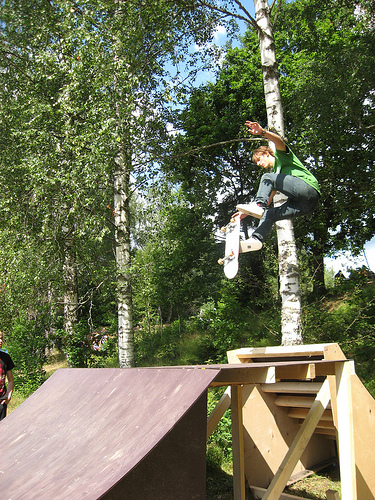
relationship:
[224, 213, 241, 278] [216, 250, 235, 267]
skateboard has wheels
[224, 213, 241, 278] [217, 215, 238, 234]
skateboard has wheels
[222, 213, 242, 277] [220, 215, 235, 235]
skateboard has two wheels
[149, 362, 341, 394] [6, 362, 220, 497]
platform near ramp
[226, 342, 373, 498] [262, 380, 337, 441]
ramp has steps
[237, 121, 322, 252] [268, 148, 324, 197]
skateboarder wearing green t-shirt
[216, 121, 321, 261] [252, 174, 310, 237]
man wearing jeans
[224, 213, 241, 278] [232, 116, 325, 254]
skateboard under boy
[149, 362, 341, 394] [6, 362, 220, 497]
platform beside ramp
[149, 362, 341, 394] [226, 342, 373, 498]
platform beside ramp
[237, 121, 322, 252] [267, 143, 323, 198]
skateboarder wearing green shirt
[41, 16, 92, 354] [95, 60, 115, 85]
birch tree has leaves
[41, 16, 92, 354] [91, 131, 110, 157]
birch tree has leaves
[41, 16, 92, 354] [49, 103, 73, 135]
birch tree has leaves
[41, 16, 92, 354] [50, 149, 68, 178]
birch tree has leaves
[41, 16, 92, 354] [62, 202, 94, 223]
birch tree has leaves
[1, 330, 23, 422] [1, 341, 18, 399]
boy wearing t-shirt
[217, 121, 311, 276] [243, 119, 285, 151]
man has arm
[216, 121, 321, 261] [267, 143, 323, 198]
man wearing green shirt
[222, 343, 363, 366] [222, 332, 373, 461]
stairs made of wood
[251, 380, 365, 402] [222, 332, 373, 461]
stairs made of wood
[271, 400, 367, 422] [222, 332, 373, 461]
stairs made of wood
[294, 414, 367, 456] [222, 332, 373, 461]
stairs made of wood